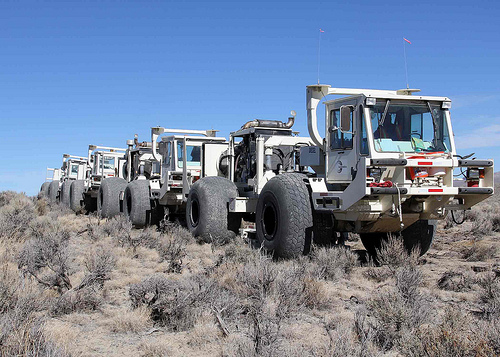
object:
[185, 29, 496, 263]
machine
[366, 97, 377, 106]
headlight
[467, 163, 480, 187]
fire extinguisher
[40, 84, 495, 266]
trucks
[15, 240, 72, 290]
scrub brush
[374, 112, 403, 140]
man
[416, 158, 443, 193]
reflectors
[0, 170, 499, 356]
ground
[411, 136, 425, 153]
paper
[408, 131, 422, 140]
steering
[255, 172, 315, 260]
tire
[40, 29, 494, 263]
convoy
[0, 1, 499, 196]
skies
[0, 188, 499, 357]
sagebrush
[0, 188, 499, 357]
desert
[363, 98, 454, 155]
window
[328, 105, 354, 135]
mirror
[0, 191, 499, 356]
dirt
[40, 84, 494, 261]
cars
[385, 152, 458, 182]
bar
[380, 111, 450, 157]
vest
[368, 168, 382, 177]
headlight